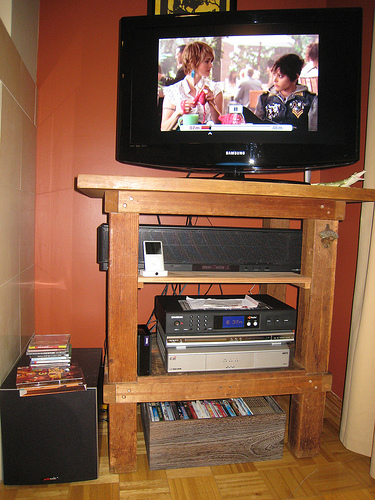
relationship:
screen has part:
[148, 32, 322, 141] [257, 26, 330, 138]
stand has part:
[66, 173, 370, 471] [276, 176, 350, 456]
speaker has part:
[0, 336, 99, 486] [8, 394, 90, 481]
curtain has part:
[337, 44, 374, 478] [337, 204, 373, 486]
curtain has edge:
[337, 44, 374, 478] [337, 204, 373, 486]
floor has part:
[232, 467, 352, 497] [269, 462, 371, 499]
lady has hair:
[166, 44, 231, 121] [177, 41, 215, 74]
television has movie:
[108, 11, 368, 178] [148, 32, 322, 141]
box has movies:
[143, 405, 281, 468] [149, 400, 258, 418]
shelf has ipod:
[133, 271, 305, 286] [140, 240, 167, 280]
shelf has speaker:
[133, 271, 305, 286] [101, 229, 324, 274]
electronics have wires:
[112, 14, 346, 376] [153, 282, 228, 296]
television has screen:
[108, 11, 368, 178] [148, 32, 322, 141]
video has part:
[148, 32, 322, 141] [257, 26, 330, 138]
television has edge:
[108, 11, 368, 178] [113, 9, 364, 27]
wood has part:
[108, 377, 329, 403] [276, 176, 350, 456]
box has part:
[143, 405, 281, 468] [233, 417, 282, 463]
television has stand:
[108, 11, 368, 178] [66, 173, 370, 471]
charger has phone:
[140, 264, 169, 278] [142, 241, 163, 270]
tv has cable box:
[108, 11, 368, 178] [155, 296, 300, 333]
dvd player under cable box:
[165, 345, 298, 375] [155, 296, 300, 333]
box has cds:
[143, 405, 281, 468] [149, 400, 258, 418]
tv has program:
[108, 11, 368, 178] [148, 32, 322, 141]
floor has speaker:
[232, 467, 352, 497] [0, 336, 99, 486]